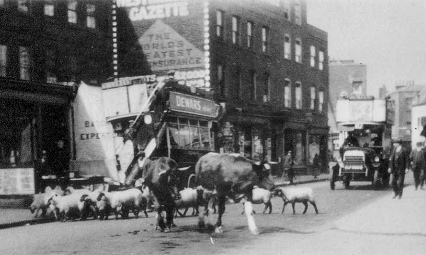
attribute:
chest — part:
[223, 175, 254, 193]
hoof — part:
[242, 201, 262, 232]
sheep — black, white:
[266, 185, 328, 217]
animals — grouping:
[40, 164, 324, 237]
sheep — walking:
[272, 185, 320, 217]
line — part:
[307, 205, 387, 253]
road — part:
[0, 172, 425, 254]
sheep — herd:
[273, 180, 320, 215]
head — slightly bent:
[150, 158, 184, 194]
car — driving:
[316, 94, 401, 191]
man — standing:
[360, 140, 425, 202]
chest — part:
[227, 181, 251, 198]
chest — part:
[155, 185, 168, 200]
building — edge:
[45, 16, 396, 202]